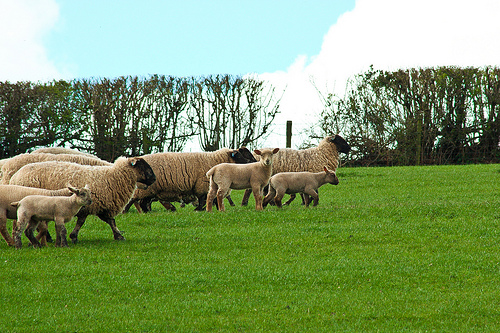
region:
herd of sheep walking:
[7, 124, 349, 236]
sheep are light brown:
[39, 131, 328, 231]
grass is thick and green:
[78, 181, 486, 323]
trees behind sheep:
[326, 66, 485, 156]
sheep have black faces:
[130, 163, 166, 185]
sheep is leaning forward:
[264, 163, 348, 206]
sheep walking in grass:
[73, 127, 460, 302]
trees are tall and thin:
[321, 71, 498, 152]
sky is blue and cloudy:
[170, 0, 358, 80]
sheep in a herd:
[2, 141, 354, 223]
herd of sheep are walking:
[20, 108, 340, 231]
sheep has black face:
[313, 129, 365, 163]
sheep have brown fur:
[262, 136, 326, 196]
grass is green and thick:
[32, 175, 492, 332]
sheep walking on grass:
[32, 128, 334, 252]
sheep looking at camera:
[218, 152, 277, 216]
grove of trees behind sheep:
[5, 72, 260, 136]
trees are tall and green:
[321, 73, 497, 153]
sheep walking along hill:
[7, 121, 433, 303]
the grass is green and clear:
[167, 157, 359, 327]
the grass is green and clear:
[224, 140, 441, 325]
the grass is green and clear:
[204, 185, 321, 319]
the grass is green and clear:
[216, 243, 314, 326]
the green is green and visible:
[236, 192, 333, 309]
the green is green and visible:
[230, 112, 385, 313]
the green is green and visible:
[216, 198, 303, 284]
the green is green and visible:
[294, 223, 359, 328]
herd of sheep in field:
[0, 138, 362, 250]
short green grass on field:
[31, 194, 483, 331]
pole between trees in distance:
[276, 114, 298, 149]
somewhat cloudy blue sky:
[6, 10, 496, 71]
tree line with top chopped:
[11, 82, 498, 185]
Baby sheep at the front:
[262, 165, 332, 207]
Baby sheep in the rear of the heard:
[8, 182, 105, 258]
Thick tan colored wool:
[162, 155, 204, 185]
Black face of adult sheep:
[323, 125, 369, 163]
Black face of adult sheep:
[233, 139, 264, 166]